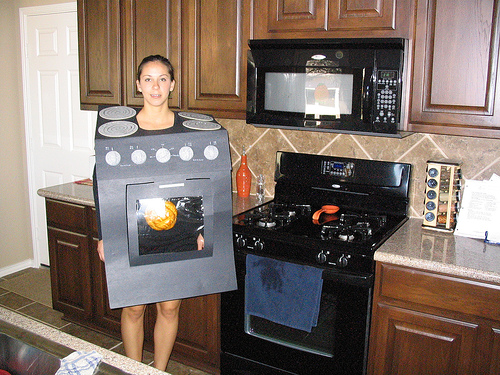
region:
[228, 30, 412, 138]
black microwave over black stove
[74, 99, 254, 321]
black stove costume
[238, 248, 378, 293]
black handle on front of stove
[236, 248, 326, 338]
blue towel on black rack on front of black stove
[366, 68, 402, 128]
control panel on front of microwave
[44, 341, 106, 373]
blue and white rag on countertop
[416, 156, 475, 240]
wooden season rack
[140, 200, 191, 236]
picture of cinnamon bun on front of stove costume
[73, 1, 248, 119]
brown wooden cabinets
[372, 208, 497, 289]
tan granite countertops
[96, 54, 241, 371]
a woman wearing a stove costume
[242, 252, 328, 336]
a blue towel hanging on the stove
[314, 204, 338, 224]
a red spoon rest on the stove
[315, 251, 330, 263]
a knob on the stove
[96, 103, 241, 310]
a stove costume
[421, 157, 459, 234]
a spice rack on the counter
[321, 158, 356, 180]
the controls for the oven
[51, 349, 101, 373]
a towel on the sink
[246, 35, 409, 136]
a black microwave above the stove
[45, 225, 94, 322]
a brown cabinet door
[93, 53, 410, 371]
woman posing next to a stove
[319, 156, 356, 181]
black oven has a digital display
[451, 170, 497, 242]
papers being held in place by a holder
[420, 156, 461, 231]
spice rack with several small bottles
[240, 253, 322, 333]
blue towel hung from oven door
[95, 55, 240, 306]
woman is wearing an oven costume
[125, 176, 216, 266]
woman's "oven" door has a clear plastic panel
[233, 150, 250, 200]
orange bottle on counter-top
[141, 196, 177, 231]
object resembling a "bun" in woman's "oven"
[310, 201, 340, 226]
orange spoon rest on stove-top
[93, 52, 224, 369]
the woman wearing the costume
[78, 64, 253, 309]
the range costume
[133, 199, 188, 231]
the bun on the costume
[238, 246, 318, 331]
the blue towel on the handle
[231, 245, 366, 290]
the handle of the oven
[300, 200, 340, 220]
the spoon on the stove top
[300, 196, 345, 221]
the spoon is orange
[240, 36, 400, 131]
the microwave over the range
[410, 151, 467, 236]
the spice rack on the counter top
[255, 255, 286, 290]
the stain on the towel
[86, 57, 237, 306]
a woman is wearing a costume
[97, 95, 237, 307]
the costume is a stove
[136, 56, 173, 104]
the woman has her hair pulled back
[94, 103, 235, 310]
the stove is grey in color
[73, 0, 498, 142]
the cabinets are against the wall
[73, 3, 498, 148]
the cabinets are made of wood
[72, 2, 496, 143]
the cabinets are brown in color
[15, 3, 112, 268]
the door is made of wood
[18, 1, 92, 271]
the door is painted white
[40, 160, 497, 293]
the counter top is made of granite